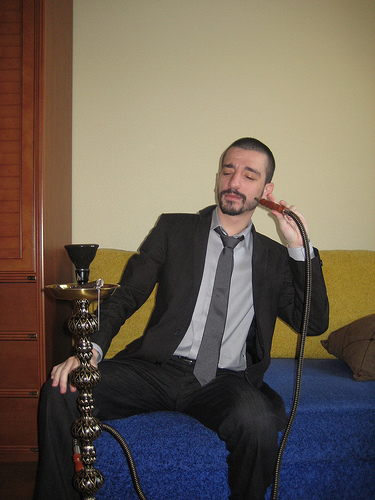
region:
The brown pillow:
[322, 301, 369, 398]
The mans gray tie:
[190, 232, 243, 397]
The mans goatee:
[216, 189, 244, 217]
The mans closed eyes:
[221, 165, 261, 182]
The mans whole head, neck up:
[207, 135, 274, 212]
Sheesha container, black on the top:
[57, 240, 97, 285]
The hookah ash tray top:
[42, 277, 111, 308]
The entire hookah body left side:
[42, 227, 105, 497]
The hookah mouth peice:
[251, 195, 284, 212]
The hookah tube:
[280, 213, 312, 490]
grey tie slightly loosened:
[194, 227, 243, 386]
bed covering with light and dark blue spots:
[74, 356, 372, 497]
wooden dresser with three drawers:
[0, 0, 72, 460]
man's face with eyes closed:
[215, 134, 275, 213]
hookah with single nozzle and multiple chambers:
[41, 195, 310, 498]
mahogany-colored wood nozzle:
[253, 195, 288, 214]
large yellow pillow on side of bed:
[74, 247, 374, 357]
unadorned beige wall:
[73, 2, 374, 248]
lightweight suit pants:
[36, 353, 281, 499]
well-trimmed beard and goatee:
[214, 182, 267, 213]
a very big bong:
[53, 216, 147, 430]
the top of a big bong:
[64, 225, 120, 284]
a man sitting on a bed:
[99, 152, 352, 438]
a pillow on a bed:
[292, 285, 367, 389]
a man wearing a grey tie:
[165, 220, 287, 415]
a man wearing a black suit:
[76, 11, 349, 397]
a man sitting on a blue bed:
[65, 193, 344, 486]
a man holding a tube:
[261, 200, 326, 265]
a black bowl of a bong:
[56, 225, 117, 281]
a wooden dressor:
[13, 197, 79, 432]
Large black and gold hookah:
[43, 195, 311, 498]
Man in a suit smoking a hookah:
[35, 137, 329, 484]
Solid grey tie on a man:
[191, 225, 243, 387]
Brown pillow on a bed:
[319, 314, 373, 380]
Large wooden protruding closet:
[2, 2, 71, 465]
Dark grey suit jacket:
[80, 206, 331, 384]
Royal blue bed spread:
[84, 359, 373, 497]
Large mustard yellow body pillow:
[71, 246, 372, 357]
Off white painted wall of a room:
[72, 10, 372, 248]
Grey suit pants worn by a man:
[35, 357, 279, 497]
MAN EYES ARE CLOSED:
[243, 172, 256, 180]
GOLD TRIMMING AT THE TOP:
[72, 289, 87, 297]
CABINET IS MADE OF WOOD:
[41, 171, 49, 212]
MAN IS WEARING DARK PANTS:
[226, 392, 255, 409]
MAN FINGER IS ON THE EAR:
[267, 188, 273, 199]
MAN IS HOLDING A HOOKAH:
[269, 200, 276, 217]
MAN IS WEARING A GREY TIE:
[214, 271, 222, 318]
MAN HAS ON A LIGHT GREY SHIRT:
[231, 299, 243, 328]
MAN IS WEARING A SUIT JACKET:
[167, 249, 191, 282]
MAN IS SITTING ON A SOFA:
[116, 153, 373, 488]